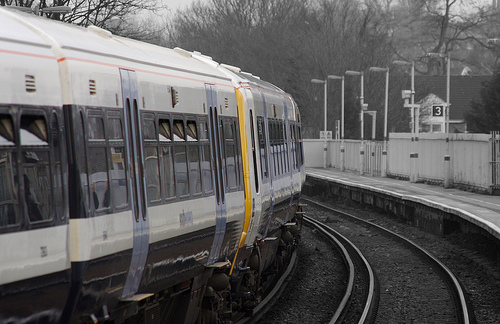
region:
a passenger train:
[2, 11, 354, 286]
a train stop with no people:
[305, 75, 490, 226]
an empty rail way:
[310, 195, 490, 315]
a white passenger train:
[0, 0, 330, 315]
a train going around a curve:
[0, 0, 330, 320]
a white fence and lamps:
[305, 60, 495, 170]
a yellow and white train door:
[230, 75, 265, 275]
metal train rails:
[306, 195, 466, 311]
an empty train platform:
[311, 146, 494, 231]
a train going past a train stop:
[3, 0, 401, 316]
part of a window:
[218, 140, 250, 175]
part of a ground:
[311, 260, 330, 291]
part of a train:
[221, 128, 258, 208]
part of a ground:
[407, 265, 429, 295]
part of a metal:
[256, 256, 261, 266]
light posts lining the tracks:
[310, 50, 472, 182]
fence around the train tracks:
[310, 123, 499, 202]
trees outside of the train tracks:
[20, 0, 499, 136]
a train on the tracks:
[2, 0, 317, 321]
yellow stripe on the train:
[234, 95, 253, 262]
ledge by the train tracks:
[305, 164, 499, 306]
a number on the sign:
[430, 98, 445, 121]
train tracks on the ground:
[273, 182, 480, 322]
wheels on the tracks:
[183, 221, 313, 322]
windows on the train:
[0, 107, 307, 240]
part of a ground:
[377, 252, 405, 304]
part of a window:
[154, 141, 199, 203]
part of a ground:
[290, 255, 347, 302]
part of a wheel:
[229, 254, 269, 292]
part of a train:
[192, 185, 250, 265]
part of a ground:
[291, 280, 313, 314]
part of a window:
[221, 154, 238, 183]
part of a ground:
[309, 280, 327, 301]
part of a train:
[229, 162, 275, 234]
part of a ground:
[383, 240, 428, 300]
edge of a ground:
[437, 196, 467, 217]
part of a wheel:
[242, 258, 282, 294]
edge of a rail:
[420, 232, 455, 293]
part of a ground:
[298, 233, 328, 260]